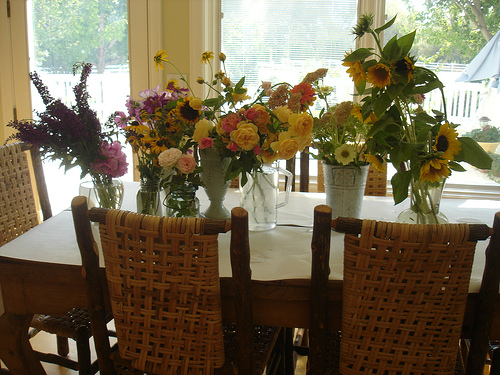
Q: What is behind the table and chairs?
A: A window.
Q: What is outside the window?
A: Seating and a deck.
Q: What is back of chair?
A: Wicker.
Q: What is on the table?
A: Bunch of flowers.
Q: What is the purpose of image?
A: Remembrance.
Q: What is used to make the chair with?
A: Wood.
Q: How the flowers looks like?
A: Fresh.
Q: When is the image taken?
A: Flowers are in vase.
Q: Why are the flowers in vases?
A: To keep fresh.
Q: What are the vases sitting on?
A: Table.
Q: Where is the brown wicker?
A: Backs of chairs.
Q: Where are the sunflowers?
A: Far right.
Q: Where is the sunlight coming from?
A: Window.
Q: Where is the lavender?
A: First vase from the left.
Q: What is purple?
A: Lavender flowers.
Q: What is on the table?
A: Flowers.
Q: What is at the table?
A: Chairs.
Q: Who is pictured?
A: No one.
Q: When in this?
A: Daytime.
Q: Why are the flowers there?
A: Decoration.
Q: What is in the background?
A: Windows.